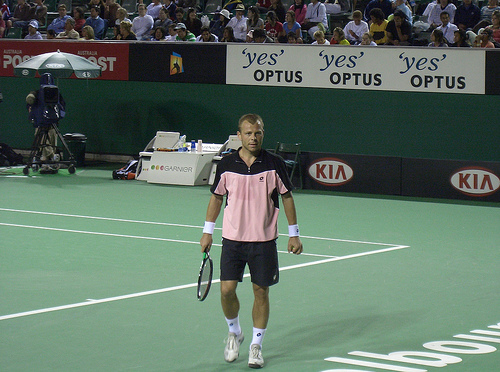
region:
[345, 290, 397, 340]
part of a court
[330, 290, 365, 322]
part of a field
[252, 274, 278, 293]
edge of a short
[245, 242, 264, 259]
part of a short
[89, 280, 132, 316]
part of a line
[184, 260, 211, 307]
edge of a racket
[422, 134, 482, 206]
part of a banner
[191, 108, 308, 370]
A TENNIS PLAYER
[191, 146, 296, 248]
A PINK AND BLACK SHIRT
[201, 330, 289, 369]
A PAIR OF TENNIS SHOES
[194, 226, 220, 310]
A BLACK TENNIS RACKET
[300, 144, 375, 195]
A RED KIA SIGN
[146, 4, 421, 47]
PEOPLE SITTING IN THE STANDS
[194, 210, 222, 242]
A WHITE WRIST BAND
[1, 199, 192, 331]
WHITE MARKINGS ON A TENNIS COURT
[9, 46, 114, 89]
A GREEN UMBRELLA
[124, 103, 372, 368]
A MAN HOLDING A TENNIS RACKET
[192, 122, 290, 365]
this is a man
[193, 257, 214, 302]
this is a racket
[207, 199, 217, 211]
the man is light skinned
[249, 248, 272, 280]
this is a short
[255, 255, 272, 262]
the short is black in color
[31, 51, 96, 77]
this is an umbrella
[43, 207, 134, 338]
this is the playing ground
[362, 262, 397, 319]
the playing ground is blue in color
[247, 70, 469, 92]
this is a writing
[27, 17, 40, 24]
this is a cap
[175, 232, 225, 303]
racket in man's hand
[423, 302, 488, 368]
writing on the floor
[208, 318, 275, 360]
white shoes and white socks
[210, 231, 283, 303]
shorts around man's waist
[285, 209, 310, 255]
white wristband on man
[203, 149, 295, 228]
light and dark shirt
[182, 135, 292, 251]
short sleeved shirt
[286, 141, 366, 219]
advertisement behind man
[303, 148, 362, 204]
red and white advertisement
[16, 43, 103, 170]
camera with an umbrella over it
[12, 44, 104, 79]
green and white umbrealla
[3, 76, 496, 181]
dark green barrier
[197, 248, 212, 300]
black tennis racket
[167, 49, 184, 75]
small yellow sign with a person on it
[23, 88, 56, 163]
person crouched behind the camera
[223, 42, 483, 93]
white banner that says yes optus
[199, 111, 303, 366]
tennis player in black and pink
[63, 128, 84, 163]
green garbage can with lid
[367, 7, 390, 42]
spectator in yellow and black shirt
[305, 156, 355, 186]
white sign that says kia in red